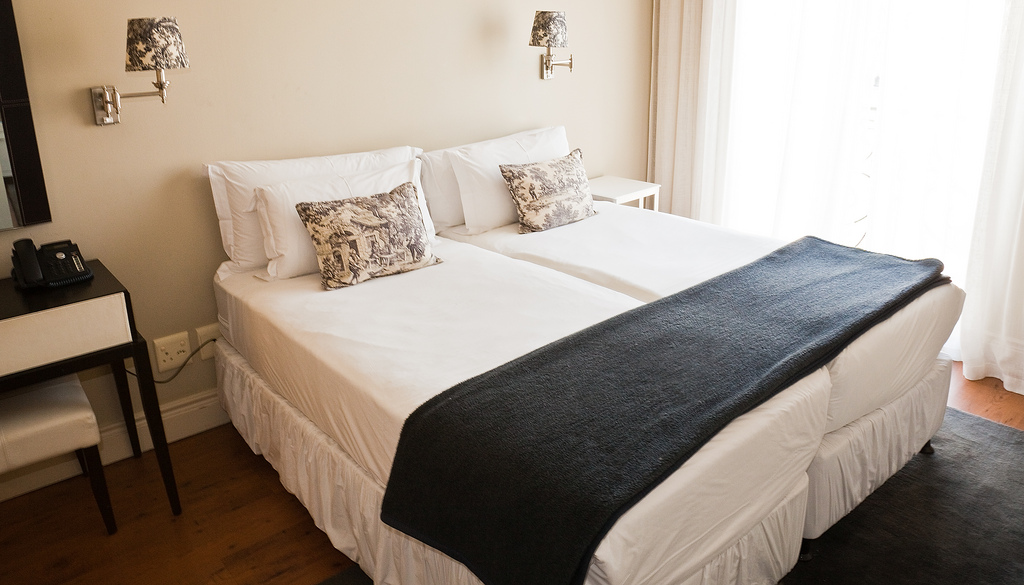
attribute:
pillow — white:
[250, 151, 460, 314]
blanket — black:
[347, 226, 963, 581]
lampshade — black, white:
[120, 14, 185, 67]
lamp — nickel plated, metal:
[87, 11, 181, 132]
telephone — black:
[16, 236, 86, 297]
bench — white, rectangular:
[0, 383, 134, 535]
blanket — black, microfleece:
[385, 238, 1023, 571]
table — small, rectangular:
[586, 175, 669, 221]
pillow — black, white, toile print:
[295, 184, 440, 290]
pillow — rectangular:
[308, 191, 434, 274]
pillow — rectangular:
[262, 184, 431, 262]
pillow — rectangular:
[206, 152, 438, 263]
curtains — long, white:
[656, 5, 732, 228]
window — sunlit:
[668, 0, 1019, 361]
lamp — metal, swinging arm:
[89, 16, 185, 133]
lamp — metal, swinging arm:
[528, 11, 580, 83]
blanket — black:
[379, 236, 933, 571]